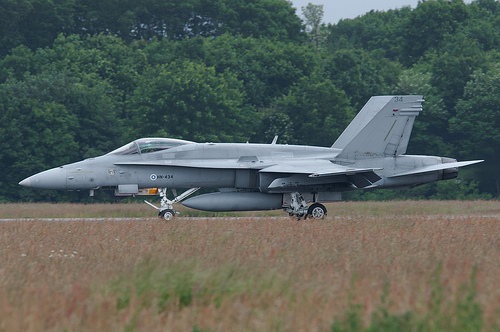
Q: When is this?
A: Daytime.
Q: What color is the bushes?
A: Green.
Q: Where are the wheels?
A: On the aircraft.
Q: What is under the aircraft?
A: Missle.